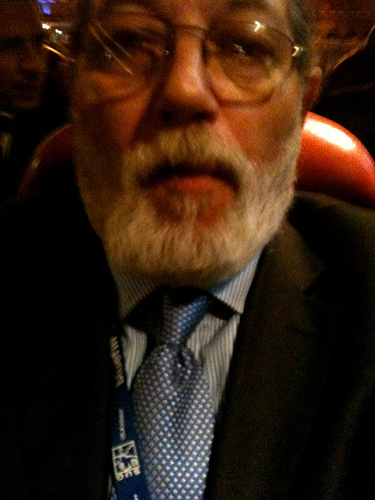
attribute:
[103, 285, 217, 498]
necktie — blue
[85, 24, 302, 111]
spectacles — clear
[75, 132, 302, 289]
beard — white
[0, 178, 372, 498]
coat — black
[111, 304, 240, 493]
tie — blue, white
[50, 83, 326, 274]
beard — white